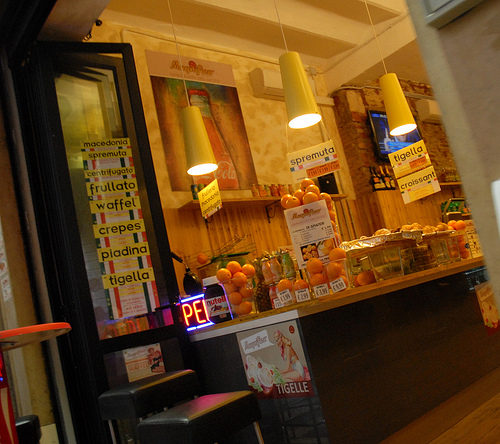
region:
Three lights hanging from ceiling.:
[171, 56, 423, 173]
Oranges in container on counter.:
[217, 261, 267, 321]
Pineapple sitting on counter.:
[251, 260, 275, 318]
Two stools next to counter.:
[92, 367, 259, 442]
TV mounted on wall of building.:
[366, 103, 433, 166]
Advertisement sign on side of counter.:
[233, 318, 328, 393]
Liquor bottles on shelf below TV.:
[363, 160, 405, 200]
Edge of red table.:
[3, 318, 73, 441]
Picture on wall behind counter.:
[140, 45, 280, 201]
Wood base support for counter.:
[317, 269, 499, 442]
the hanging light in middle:
[275, 38, 342, 139]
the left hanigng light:
[166, 67, 241, 179]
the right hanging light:
[366, 67, 419, 142]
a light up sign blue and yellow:
[175, 292, 217, 334]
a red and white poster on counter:
[233, 308, 322, 405]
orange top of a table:
[0, 311, 82, 344]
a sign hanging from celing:
[388, 130, 445, 212]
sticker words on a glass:
[68, 130, 175, 327]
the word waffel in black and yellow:
[78, 196, 149, 213]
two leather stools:
[84, 365, 263, 442]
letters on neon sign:
[175, 283, 215, 339]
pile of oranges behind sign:
[275, 171, 332, 233]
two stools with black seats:
[93, 363, 273, 440]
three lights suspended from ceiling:
[153, 53, 424, 188]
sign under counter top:
[230, 315, 318, 403]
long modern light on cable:
[272, 28, 324, 140]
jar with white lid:
[197, 272, 234, 327]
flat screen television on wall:
[358, 103, 439, 167]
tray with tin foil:
[338, 222, 433, 260]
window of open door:
[39, 61, 123, 149]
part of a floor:
[466, 415, 488, 437]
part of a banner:
[266, 343, 298, 365]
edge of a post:
[297, 355, 315, 396]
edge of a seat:
[181, 401, 238, 433]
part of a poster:
[174, 280, 209, 318]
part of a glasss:
[288, 400, 313, 424]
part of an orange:
[222, 270, 255, 317]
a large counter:
[217, 253, 492, 441]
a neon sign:
[166, 278, 223, 330]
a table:
[0, 303, 81, 438]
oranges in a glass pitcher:
[211, 250, 261, 320]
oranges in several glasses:
[265, 243, 360, 314]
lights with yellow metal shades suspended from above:
[155, 1, 425, 177]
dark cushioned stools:
[97, 356, 272, 441]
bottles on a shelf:
[359, 153, 442, 206]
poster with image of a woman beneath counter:
[235, 308, 334, 405]